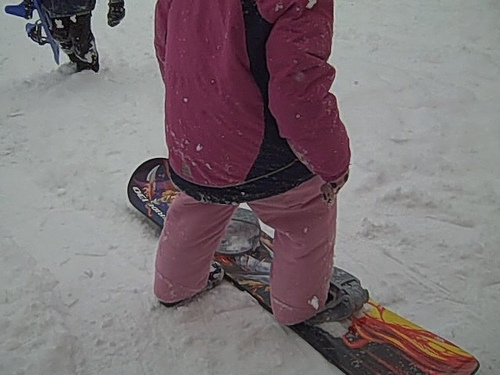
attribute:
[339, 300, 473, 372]
design — yellow, red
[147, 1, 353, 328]
boy — Litle , little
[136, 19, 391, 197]
coat — pink, black, winter coat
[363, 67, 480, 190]
snow — white